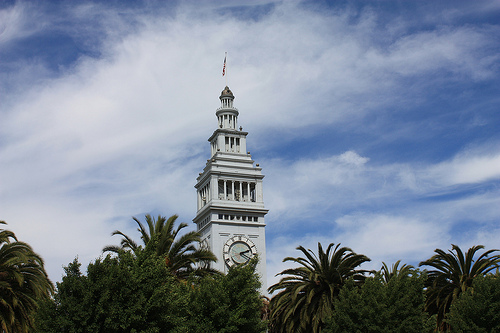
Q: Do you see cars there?
A: No, there are no cars.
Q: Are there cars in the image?
A: No, there are no cars.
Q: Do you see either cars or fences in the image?
A: No, there are no cars or fences.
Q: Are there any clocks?
A: Yes, there is a clock.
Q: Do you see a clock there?
A: Yes, there is a clock.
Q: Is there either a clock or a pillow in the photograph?
A: Yes, there is a clock.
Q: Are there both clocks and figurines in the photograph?
A: No, there is a clock but no figurines.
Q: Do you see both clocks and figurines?
A: No, there is a clock but no figurines.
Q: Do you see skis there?
A: No, there are no skis.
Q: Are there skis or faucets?
A: No, there are no skis or faucets.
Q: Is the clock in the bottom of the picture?
A: Yes, the clock is in the bottom of the image.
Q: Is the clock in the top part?
A: No, the clock is in the bottom of the image.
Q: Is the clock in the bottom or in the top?
A: The clock is in the bottom of the image.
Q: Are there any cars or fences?
A: No, there are no fences or cars.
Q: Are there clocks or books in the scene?
A: Yes, there is a clock.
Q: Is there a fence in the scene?
A: No, there are no fences.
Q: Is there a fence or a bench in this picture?
A: No, there are no fences or benches.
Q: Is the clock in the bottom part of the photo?
A: Yes, the clock is in the bottom of the image.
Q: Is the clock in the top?
A: No, the clock is in the bottom of the image.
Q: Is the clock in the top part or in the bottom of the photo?
A: The clock is in the bottom of the image.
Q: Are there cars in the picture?
A: No, there are no cars.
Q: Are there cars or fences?
A: No, there are no cars or fences.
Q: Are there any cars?
A: No, there are no cars.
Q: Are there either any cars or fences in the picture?
A: No, there are no cars or fences.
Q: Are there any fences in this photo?
A: No, there are no fences.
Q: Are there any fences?
A: No, there are no fences.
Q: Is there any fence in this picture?
A: No, there are no fences.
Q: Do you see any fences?
A: No, there are no fences.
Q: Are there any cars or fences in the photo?
A: No, there are no fences or cars.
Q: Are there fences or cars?
A: No, there are no fences or cars.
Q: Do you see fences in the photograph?
A: No, there are no fences.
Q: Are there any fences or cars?
A: No, there are no fences or cars.